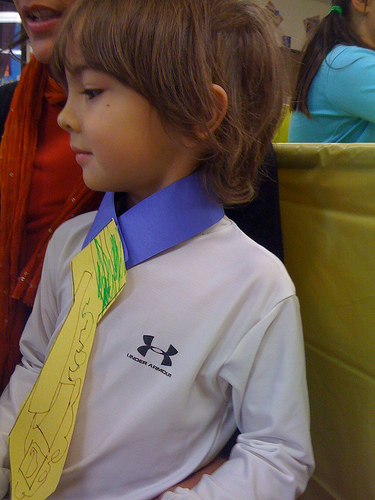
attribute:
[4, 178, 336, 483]
shirt — WHITE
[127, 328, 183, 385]
logo — DARK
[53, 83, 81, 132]
nose — Small 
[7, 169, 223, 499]
tie — yellow, paper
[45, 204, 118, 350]
tie — FAKE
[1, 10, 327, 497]
boy — little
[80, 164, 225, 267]
blue collar — paper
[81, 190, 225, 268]
collar — blue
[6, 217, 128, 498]
tie — yellow 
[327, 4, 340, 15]
ponytail holder — green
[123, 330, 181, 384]
logo — Under Armour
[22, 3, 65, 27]
mouth — open